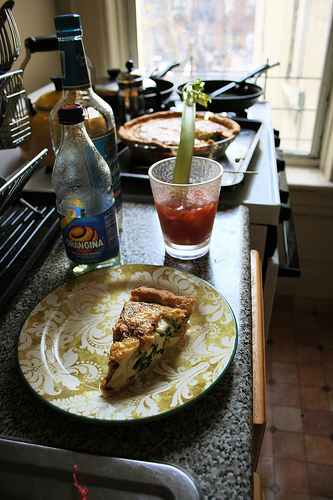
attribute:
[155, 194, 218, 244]
liquid — red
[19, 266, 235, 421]
green — white, paisley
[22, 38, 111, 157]
kettle — yellow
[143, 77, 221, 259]
cocktail — bloody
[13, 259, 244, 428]
plate — green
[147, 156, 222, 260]
glass — empty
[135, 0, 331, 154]
window — large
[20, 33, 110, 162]
kettle — yellow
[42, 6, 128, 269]
bottles — empty, glass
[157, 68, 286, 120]
pan — black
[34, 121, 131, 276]
glass bottle — empty 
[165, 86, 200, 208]
celery — stick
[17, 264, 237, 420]
pattern — ornate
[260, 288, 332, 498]
floor — shades, brown, tiled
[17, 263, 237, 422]
design — floral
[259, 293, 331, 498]
flooring — brown, tiled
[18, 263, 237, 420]
plate — green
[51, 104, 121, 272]
bottle — empty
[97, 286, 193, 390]
quiche — fresh, baked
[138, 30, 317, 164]
window — large, uncurtained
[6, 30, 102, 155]
teapot — old fashioned, yellow